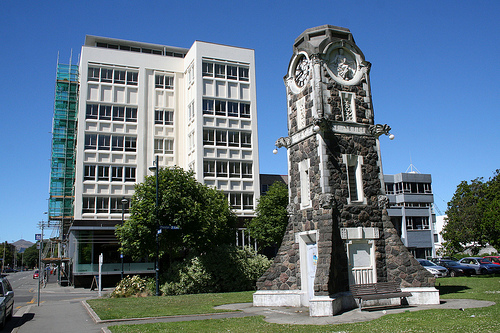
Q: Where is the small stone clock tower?
A: In the grass.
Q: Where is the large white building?
A: Behind the clock tower.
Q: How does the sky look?
A: Clear and blue.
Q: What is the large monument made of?
A: Stone.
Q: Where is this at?
A: Downtown.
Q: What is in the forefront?
A: Monument.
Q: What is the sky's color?
A: Blue.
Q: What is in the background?
A: Buildings.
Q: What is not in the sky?
A: Clouds.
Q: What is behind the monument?
A: Trees.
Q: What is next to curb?
A: Car.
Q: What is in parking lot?
A: Cars.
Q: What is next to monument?
A: Bench.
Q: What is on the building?
A: A scaffold.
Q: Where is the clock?
A: On the tower.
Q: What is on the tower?
A: A clock.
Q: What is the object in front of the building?
A: A monument.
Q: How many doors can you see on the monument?
A: Two.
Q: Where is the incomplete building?
A: Behind the white building.